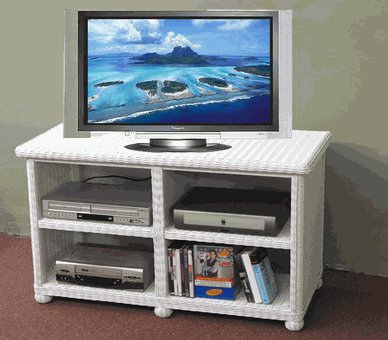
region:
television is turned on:
[55, 6, 318, 168]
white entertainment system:
[11, 96, 336, 330]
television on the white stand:
[8, 2, 338, 338]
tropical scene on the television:
[86, 14, 274, 132]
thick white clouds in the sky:
[86, 19, 162, 51]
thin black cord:
[84, 169, 154, 187]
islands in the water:
[90, 70, 245, 103]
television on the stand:
[53, 4, 300, 151]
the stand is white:
[22, 121, 311, 338]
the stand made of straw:
[10, 121, 349, 330]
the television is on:
[57, 5, 305, 147]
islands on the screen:
[93, 27, 263, 122]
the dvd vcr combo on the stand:
[40, 184, 149, 229]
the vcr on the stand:
[59, 242, 170, 296]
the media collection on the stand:
[164, 247, 282, 310]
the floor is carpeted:
[3, 236, 55, 339]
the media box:
[180, 188, 281, 230]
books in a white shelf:
[235, 247, 276, 306]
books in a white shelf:
[193, 244, 241, 304]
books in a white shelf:
[169, 248, 194, 295]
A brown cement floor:
[33, 298, 132, 339]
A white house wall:
[325, 240, 385, 285]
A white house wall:
[7, 23, 66, 126]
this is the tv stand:
[131, 123, 243, 170]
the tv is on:
[83, 5, 253, 106]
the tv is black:
[91, 83, 299, 163]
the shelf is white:
[133, 158, 303, 201]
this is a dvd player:
[91, 189, 167, 222]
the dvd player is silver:
[39, 163, 189, 228]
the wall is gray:
[317, 43, 376, 132]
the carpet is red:
[46, 303, 172, 337]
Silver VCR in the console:
[36, 242, 157, 296]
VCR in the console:
[46, 247, 156, 291]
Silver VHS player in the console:
[54, 240, 157, 293]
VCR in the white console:
[42, 245, 153, 291]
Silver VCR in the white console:
[55, 247, 161, 300]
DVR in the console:
[166, 206, 295, 239]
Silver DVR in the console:
[170, 201, 290, 238]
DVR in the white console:
[172, 202, 285, 235]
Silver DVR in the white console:
[175, 205, 281, 243]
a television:
[64, 10, 291, 139]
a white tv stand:
[23, 127, 319, 323]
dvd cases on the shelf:
[168, 244, 272, 300]